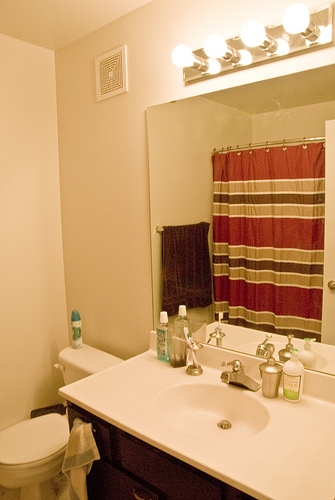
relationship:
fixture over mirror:
[163, 9, 321, 82] [145, 107, 324, 365]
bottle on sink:
[282, 348, 304, 403] [152, 357, 274, 445]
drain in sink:
[217, 418, 232, 429] [170, 382, 264, 449]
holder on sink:
[186, 341, 203, 376] [130, 358, 287, 468]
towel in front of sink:
[61, 417, 100, 498] [182, 357, 305, 474]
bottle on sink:
[153, 310, 176, 363] [152, 357, 274, 445]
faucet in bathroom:
[220, 359, 261, 391] [17, 60, 319, 491]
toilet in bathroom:
[1, 329, 123, 497] [0, 0, 334, 498]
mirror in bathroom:
[143, 60, 333, 377] [0, 0, 334, 498]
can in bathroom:
[69, 308, 82, 348] [0, 0, 334, 498]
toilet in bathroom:
[1, 342, 136, 497] [0, 0, 334, 498]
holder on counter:
[186, 341, 203, 376] [50, 311, 333, 497]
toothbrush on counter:
[179, 326, 200, 369] [50, 311, 333, 497]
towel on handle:
[63, 417, 94, 498] [88, 422, 101, 437]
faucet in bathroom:
[217, 359, 261, 391] [0, 0, 334, 498]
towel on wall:
[158, 207, 219, 320] [148, 108, 218, 330]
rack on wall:
[159, 227, 166, 234] [148, 108, 218, 330]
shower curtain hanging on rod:
[209, 141, 324, 344] [213, 135, 322, 150]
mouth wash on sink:
[155, 309, 171, 363] [154, 380, 270, 453]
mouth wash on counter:
[155, 309, 171, 363] [58, 347, 334, 498]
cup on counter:
[162, 323, 191, 367] [55, 328, 334, 498]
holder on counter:
[184, 341, 203, 375] [55, 328, 334, 498]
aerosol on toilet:
[69, 308, 83, 349] [1, 329, 123, 497]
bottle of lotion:
[281, 349, 304, 399] [286, 372, 301, 391]